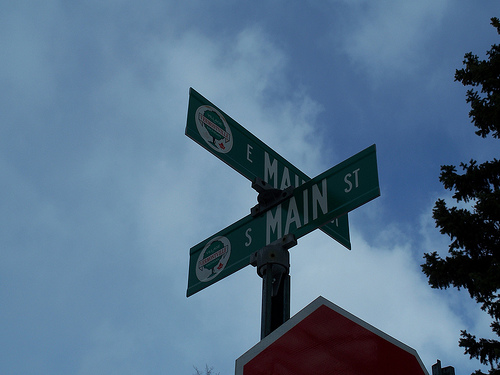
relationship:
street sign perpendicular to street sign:
[182, 85, 351, 248] [187, 139, 383, 291]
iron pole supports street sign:
[254, 230, 292, 339] [182, 85, 351, 248]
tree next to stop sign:
[416, 12, 495, 374] [231, 294, 426, 374]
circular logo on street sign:
[193, 104, 234, 152] [182, 85, 351, 248]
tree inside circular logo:
[203, 108, 228, 149] [193, 104, 234, 152]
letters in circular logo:
[198, 111, 230, 138] [193, 104, 234, 152]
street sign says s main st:
[182, 85, 351, 248] [239, 160, 368, 249]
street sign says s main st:
[187, 139, 383, 291] [239, 160, 368, 249]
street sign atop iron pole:
[182, 85, 351, 248] [254, 230, 292, 339]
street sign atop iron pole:
[187, 139, 383, 291] [254, 230, 292, 339]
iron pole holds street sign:
[254, 230, 292, 339] [182, 85, 351, 248]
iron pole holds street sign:
[254, 230, 292, 339] [187, 139, 383, 291]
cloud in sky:
[1, 1, 466, 374] [1, 1, 499, 373]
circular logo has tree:
[193, 104, 234, 152] [203, 108, 228, 149]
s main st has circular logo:
[239, 160, 368, 249] [193, 104, 234, 152]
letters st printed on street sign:
[344, 169, 362, 194] [187, 139, 383, 291]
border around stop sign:
[234, 298, 420, 374] [231, 294, 426, 374]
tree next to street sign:
[416, 12, 495, 374] [182, 85, 351, 248]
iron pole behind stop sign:
[254, 230, 292, 339] [231, 294, 426, 374]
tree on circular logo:
[203, 108, 228, 149] [193, 104, 234, 152]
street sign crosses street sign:
[182, 85, 351, 248] [187, 139, 383, 291]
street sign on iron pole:
[182, 85, 351, 248] [254, 230, 292, 339]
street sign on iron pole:
[187, 139, 383, 291] [254, 230, 292, 339]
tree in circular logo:
[203, 108, 228, 149] [193, 104, 234, 152]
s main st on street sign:
[239, 160, 368, 249] [182, 85, 351, 248]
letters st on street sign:
[344, 169, 362, 194] [182, 85, 351, 248]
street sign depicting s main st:
[182, 85, 351, 248] [239, 160, 368, 249]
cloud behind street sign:
[1, 1, 466, 374] [182, 85, 351, 248]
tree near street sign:
[416, 12, 495, 374] [182, 85, 351, 248]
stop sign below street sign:
[231, 294, 426, 374] [182, 85, 351, 248]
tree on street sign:
[203, 108, 228, 149] [182, 85, 351, 248]